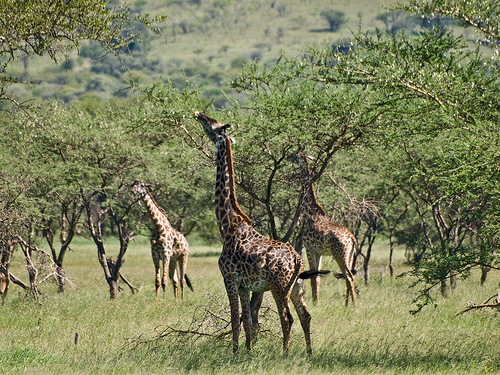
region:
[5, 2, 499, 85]
A hill in the distance.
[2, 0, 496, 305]
Grove of trees in a field.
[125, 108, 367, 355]
Giraffes grazing in a field.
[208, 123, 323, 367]
One giraffe in a pasture.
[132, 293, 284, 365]
Tree branch on the ground.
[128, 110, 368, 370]
Three giraffes in a field.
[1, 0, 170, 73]
Leaves on a tree.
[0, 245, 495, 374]
Green grass in a field.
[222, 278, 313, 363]
Legs of a giraffe.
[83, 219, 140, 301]
Tree trunk of a tree.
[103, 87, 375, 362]
giraffes standing in grass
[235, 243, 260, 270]
brown spots on giraffe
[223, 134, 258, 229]
brown giraffe mane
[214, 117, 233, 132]
ossicones on top of giraffe head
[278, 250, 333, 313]
giraffe tail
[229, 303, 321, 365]
giraffe legs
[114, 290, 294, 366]
fallen branches on ground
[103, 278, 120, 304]
tree trunk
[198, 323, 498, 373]
shadow of giraffe on ground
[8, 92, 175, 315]
green trees in field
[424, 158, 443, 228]
There are some green trees here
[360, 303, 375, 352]
There is some light green grass here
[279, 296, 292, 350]
There is a giraffe tail here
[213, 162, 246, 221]
There is a long giraffe neck here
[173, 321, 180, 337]
There are tree limbs here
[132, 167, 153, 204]
This giraffe has a large head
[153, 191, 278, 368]
This photo has a great deal of detail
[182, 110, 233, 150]
head of the giraffe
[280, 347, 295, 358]
hoof of the giraffe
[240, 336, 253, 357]
hoof of the giraffe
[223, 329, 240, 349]
hoof of the giraffe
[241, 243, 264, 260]
spots on the giraffe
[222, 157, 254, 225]
mane of the giraffe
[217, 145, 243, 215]
neck of the giraffe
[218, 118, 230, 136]
ear of the giraffe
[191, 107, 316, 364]
giraffe closest to the camera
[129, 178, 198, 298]
giraffe in the most sun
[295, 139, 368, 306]
giraffe with head and neck hidden in the tree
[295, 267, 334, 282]
black giraffe tail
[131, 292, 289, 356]
brown branches on the ground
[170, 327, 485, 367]
shadow on the ground under the giraffe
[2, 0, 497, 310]
trees around the giraffes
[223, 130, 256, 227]
brown giraffe neck hair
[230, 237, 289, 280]
brown giraffe spots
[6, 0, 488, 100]
blurry trees in the background